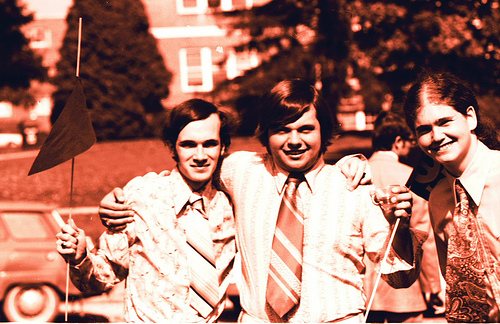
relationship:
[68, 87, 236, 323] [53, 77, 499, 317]
men looking at camera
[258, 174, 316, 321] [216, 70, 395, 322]
tie of middle man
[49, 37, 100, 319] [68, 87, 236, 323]
flag held by man on left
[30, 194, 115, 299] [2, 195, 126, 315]
end of car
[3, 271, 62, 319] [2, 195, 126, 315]
tire on car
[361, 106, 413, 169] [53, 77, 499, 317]
man facing away camera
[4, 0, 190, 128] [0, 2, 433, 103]
trees in front of building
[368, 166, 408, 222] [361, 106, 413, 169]
cup in middle man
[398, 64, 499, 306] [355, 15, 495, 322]
man on right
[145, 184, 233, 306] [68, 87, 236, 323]
tie on guy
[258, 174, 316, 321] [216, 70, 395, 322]
tie on middle guy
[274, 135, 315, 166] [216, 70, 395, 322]
smile on middle guy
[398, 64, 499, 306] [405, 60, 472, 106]
guy with hairdo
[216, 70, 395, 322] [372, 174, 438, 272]
guy hold black flag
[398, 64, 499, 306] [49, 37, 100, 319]
man holding flag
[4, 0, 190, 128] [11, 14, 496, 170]
trees in background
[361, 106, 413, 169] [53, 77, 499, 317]
man behind scene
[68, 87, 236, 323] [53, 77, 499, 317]
friend having fun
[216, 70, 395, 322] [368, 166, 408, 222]
man holding cup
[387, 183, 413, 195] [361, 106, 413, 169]
ring on person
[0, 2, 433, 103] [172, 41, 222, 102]
building has window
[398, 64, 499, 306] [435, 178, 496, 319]
man has tie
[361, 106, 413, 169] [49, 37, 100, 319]
man holding flag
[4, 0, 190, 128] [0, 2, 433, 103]
trees behind building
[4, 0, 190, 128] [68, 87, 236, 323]
trees behind men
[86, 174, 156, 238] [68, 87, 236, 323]
arm around man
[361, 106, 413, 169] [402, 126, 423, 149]
man wearing glasses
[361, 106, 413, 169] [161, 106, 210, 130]
man with hair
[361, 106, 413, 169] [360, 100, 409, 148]
person with hair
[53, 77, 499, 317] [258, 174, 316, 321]
friends wearing ties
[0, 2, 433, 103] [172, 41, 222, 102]
building with window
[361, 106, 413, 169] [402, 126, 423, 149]
man with glasses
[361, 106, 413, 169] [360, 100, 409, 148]
man with hair